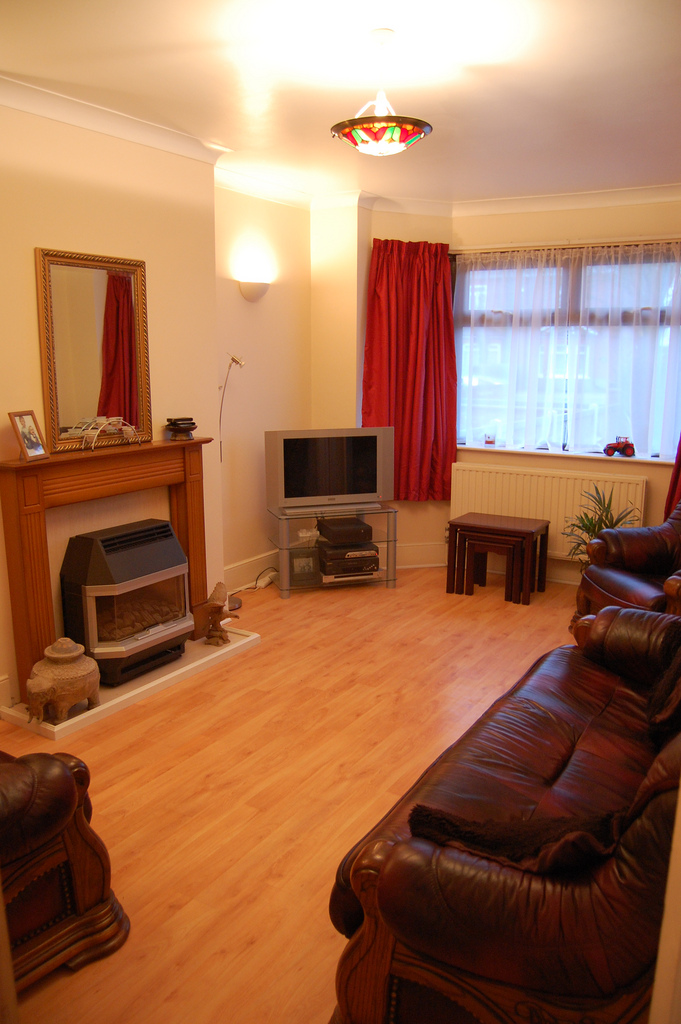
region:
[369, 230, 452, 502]
A red curtain hanging to the side of the window.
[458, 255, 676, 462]
Clear curtains hanging in the window.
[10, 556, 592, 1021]
Hardwood floors.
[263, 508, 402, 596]
A grey entertainment stand.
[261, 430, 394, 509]
A silver framed television.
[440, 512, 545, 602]
Wooden end tables.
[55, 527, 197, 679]
A black and grey fireplace.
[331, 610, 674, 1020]
A brown leather sofa.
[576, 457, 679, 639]
A brown leather armchair.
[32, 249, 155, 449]
A golden framed mirror hanging over the fireplace.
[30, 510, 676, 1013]
WOODEN FLOOR IN LIVING ROOM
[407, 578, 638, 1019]
LARGE MAROON COUCH IN LIVING ROOM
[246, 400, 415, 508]
GRAY AND BLACK TELEVISION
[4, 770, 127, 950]
EDGE OF BROWN LEATHER COUCH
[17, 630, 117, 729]
SMALL ELEPHANT POTTERY BY FIREPLACE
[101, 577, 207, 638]
ROCKS AND LOGS IN FIREPLACE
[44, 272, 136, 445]
MIRROR OVER FIREPLACE MANTLE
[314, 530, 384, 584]
DVD PLAYER UNDER TV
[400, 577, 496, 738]
LIGHT REFLECTING ON WOOD FLOOR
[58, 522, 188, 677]
The portable fireplace.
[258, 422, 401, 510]
The flat television.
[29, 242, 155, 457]
The large mirror on the mantle.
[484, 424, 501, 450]
The glass on the window sill.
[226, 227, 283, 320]
The light on the wall.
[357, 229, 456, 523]
The red curtain on the window.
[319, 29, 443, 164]
The light on the ceiling.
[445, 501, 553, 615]
The group of end tables.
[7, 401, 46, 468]
The picture on the wall.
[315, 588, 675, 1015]
A brown leather couch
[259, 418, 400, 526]
A television set is turned off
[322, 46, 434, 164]
A light fixture hanging from the ceiling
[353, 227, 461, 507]
The curtains are colored red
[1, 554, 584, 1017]
A brown wooden floor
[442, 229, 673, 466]
White curtains over a window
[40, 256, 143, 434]
Reflections in the mirror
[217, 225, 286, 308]
A light is turned on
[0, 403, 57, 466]
A wooden photo frame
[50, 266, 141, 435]
glass is clean and clear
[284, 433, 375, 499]
glass is clean and clear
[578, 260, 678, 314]
glass is clean and clear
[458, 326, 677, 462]
glass is clean and clear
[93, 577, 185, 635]
glass is clean and clear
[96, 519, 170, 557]
glass is clean and clear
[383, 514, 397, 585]
tv stand has a leg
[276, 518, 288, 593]
tv stand has a leg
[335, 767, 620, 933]
A cushion on a couch.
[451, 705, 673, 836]
A cushion on a couch.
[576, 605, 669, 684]
A cushion on a couch.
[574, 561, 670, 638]
A cushion on a couch.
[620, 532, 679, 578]
A cushion on a couch.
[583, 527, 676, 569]
A cushion on a couch.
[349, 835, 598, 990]
A cushion on a couch.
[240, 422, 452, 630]
silver tv on tv stand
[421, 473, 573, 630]
wooden tables in living room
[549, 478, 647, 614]
pot plant on floor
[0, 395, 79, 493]
framed picture on mantel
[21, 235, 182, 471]
framed mirror on wall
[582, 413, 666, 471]
toy car on window sill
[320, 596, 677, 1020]
brown leather couch in living room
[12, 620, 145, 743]
elephant ornament next to fireplace